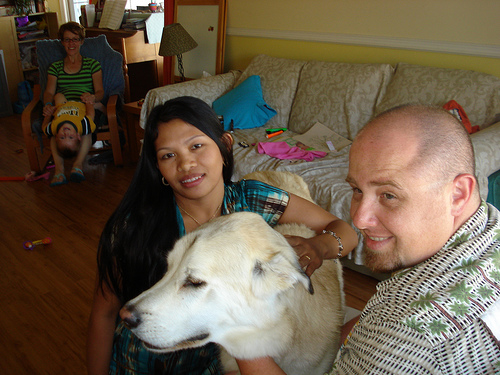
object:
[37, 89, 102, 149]
child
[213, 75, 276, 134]
pillow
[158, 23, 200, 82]
lamp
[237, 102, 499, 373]
man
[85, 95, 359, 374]
woman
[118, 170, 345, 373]
dog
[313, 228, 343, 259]
bracelet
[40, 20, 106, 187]
woman child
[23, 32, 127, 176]
rocking chair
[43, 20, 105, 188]
woman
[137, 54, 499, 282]
sofa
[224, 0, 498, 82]
wall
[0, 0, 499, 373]
living room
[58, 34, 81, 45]
glasses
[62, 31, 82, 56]
woman's face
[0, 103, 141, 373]
floor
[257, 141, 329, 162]
pink cloth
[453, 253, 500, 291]
palm trees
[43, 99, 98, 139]
shirt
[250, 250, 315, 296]
ears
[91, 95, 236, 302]
hair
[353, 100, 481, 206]
hair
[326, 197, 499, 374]
shirt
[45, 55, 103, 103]
shirt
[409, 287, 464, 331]
palm trees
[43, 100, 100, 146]
lap